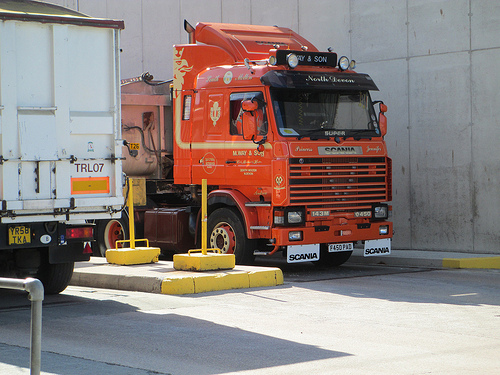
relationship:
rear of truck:
[3, 13, 121, 217] [4, 1, 126, 296]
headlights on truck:
[281, 204, 388, 244] [125, 11, 399, 273]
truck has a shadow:
[125, 11, 399, 273] [81, 289, 373, 370]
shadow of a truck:
[282, 257, 499, 306] [125, 11, 399, 273]